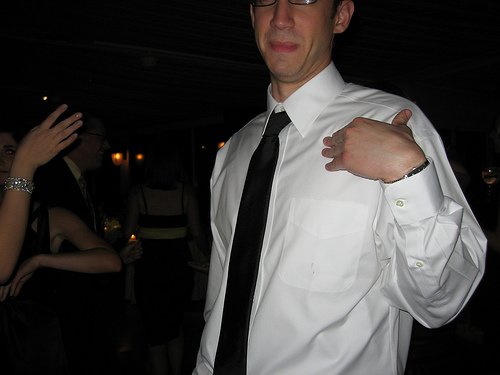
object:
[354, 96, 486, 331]
arm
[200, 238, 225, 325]
arm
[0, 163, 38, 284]
arm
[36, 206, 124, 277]
arm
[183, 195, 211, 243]
arm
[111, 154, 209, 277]
person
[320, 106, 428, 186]
hand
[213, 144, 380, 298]
chest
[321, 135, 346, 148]
finger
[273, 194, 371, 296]
pocket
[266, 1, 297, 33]
nose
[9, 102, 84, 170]
hand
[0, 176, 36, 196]
bracelet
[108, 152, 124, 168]
candles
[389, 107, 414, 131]
thumb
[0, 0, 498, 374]
background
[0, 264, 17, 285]
elbow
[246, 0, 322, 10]
eyeglasses.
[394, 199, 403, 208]
button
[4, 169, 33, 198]
wrist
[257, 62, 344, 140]
collar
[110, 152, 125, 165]
light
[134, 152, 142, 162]
light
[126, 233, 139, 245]
light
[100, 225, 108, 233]
light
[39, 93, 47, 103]
light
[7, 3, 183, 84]
air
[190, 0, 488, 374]
man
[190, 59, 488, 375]
shirt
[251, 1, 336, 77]
face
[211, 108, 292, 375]
necktie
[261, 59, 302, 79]
jaw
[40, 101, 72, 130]
finger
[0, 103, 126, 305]
person